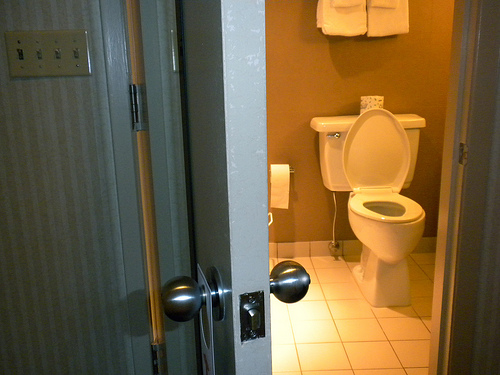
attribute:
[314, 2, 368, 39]
towel — hanging, white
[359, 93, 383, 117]
toilet paper — white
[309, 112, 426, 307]
toilet — white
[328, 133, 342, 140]
lever — silver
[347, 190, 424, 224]
seat — white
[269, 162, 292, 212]
toilet paper — white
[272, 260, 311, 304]
doorknob — silver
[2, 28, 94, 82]
light switches — beige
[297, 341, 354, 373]
tile — white, square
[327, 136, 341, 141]
handle — silver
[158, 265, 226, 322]
handle — silver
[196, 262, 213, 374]
hanger — white